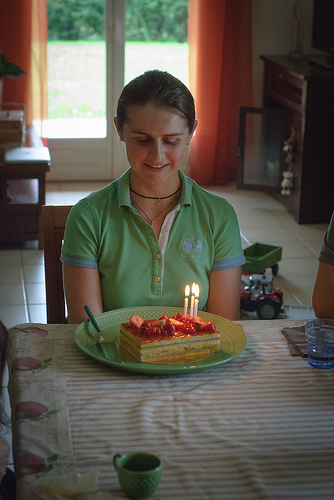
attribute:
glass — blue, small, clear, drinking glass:
[304, 317, 333, 372]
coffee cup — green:
[110, 445, 170, 492]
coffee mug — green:
[113, 447, 167, 494]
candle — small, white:
[178, 282, 193, 320]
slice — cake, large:
[116, 308, 225, 359]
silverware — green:
[81, 300, 121, 367]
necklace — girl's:
[132, 180, 188, 219]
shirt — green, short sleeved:
[56, 175, 253, 316]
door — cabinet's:
[235, 107, 292, 192]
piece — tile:
[241, 201, 289, 230]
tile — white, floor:
[243, 205, 286, 256]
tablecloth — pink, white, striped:
[4, 316, 333, 487]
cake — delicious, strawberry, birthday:
[115, 309, 226, 361]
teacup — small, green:
[105, 446, 172, 497]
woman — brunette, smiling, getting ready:
[57, 66, 274, 322]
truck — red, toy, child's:
[244, 271, 286, 312]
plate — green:
[72, 297, 250, 373]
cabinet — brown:
[231, 53, 333, 224]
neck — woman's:
[133, 173, 185, 213]